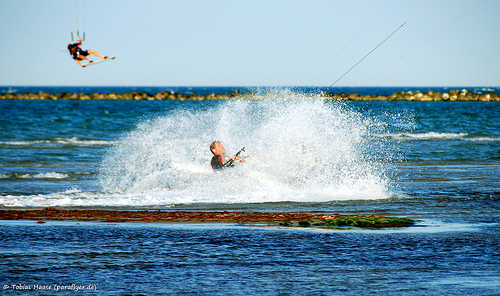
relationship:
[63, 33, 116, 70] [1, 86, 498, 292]
man over water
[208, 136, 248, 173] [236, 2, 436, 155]
man holding onto rope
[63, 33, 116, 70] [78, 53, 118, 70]
man on top of water skii board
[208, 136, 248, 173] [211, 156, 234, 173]
man wearing wetsuit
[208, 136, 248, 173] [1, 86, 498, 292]
man skiing in water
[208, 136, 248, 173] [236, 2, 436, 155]
man being pulled with rope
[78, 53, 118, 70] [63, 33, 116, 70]
water skii board under man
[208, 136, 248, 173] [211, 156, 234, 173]
man wearing a wetsuit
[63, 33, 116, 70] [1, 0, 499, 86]
man hanging in sky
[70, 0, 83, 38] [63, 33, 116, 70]
string supporting man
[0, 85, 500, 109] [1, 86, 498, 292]
barrier in center of water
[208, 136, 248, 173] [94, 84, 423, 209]
man makes splash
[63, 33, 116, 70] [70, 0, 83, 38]
man hangs on string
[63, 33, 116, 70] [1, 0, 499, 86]
man in sky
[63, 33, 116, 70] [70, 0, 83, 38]
man attached to string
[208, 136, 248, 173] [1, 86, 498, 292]
man in water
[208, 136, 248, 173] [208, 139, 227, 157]
man has head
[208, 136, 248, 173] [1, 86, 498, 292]
man surfing in water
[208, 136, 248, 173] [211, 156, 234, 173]
man has wetsuit